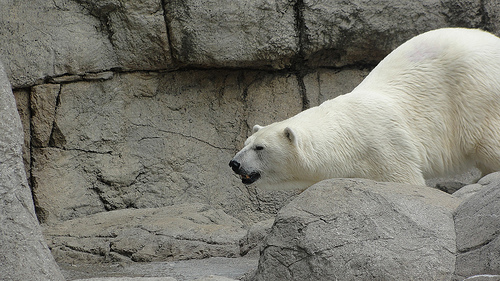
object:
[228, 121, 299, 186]
head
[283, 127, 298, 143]
ear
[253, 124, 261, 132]
ear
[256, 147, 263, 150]
eye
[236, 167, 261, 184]
mouth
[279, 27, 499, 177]
body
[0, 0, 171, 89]
rock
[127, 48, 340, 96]
shadow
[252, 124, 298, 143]
two ears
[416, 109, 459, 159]
fur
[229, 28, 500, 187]
bear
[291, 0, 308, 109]
line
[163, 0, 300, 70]
rock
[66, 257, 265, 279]
floor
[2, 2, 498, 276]
bear pen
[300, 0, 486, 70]
rock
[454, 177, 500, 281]
rock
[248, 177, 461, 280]
rock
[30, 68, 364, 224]
rock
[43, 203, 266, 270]
rock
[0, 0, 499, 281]
zoo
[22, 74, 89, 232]
cracks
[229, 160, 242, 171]
nose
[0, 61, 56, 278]
rocks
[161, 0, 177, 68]
lines